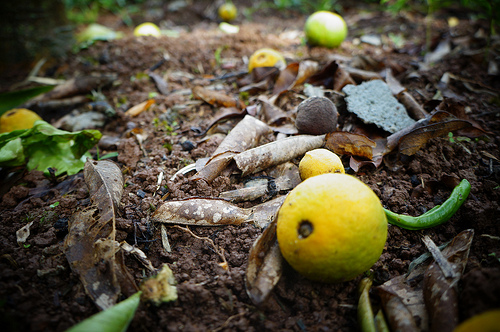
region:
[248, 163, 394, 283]
yellow object on ground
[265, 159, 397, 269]
yellow lemon on the ground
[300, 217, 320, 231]
brown end of lemon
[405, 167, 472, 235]
green leaf on ground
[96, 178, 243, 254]
brown leaves on the ground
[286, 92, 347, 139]
brown acorn on the ground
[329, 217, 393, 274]
green tint to lemon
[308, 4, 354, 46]
green oject on ground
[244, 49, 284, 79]
yellow lemon on the ground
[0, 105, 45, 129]
yellow lemon on the ground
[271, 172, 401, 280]
a round yellow fruit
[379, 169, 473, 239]
a green long leaf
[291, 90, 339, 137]
a brown coconut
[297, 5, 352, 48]
a round green fruit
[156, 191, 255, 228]
a long brown leaf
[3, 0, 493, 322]
wet and dark brown dirt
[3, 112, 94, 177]
a large green leaf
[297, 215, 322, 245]
a stem connector on a fruit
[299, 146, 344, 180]
a round yellow fruit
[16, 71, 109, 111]
a brown stick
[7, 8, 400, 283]
Pieces of fruit on the ground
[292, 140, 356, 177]
This is a lemon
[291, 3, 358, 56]
This is a green apple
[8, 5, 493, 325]
The ground is made of dirt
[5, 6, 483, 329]
The ground is wet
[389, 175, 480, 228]
This leaf is curled up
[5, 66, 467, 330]
Many leaves on the ground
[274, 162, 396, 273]
A round yellow fruit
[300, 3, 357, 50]
The apple is round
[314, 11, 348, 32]
Light is shining on the apple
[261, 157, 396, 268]
crabapple on the brown ground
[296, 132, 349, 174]
crabapple on the brown ground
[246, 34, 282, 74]
crabapple on the brown ground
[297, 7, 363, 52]
green crabapple on the brown ground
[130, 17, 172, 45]
yellow crabapple on the brown ground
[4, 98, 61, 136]
crabapple on the brown ground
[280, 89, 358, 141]
brown crabapple on the brown ground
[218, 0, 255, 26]
yellow crabapple on the brown ground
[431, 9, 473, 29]
crabapple on the brown ground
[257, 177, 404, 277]
yellow crabapple on the brown ground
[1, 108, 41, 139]
a round yellow fruit on the ground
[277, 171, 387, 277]
a round yellow fruit on the ground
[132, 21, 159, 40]
a round yellow fruit on the ground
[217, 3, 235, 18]
a round yellow fruit on the ground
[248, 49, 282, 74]
a round yellow fruit on the ground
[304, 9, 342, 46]
a round yellow fruit on the ground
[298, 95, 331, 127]
a brown fruit on the ground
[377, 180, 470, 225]
a bright green leaf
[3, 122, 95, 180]
a bright green leaf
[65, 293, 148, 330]
a bright green leaf